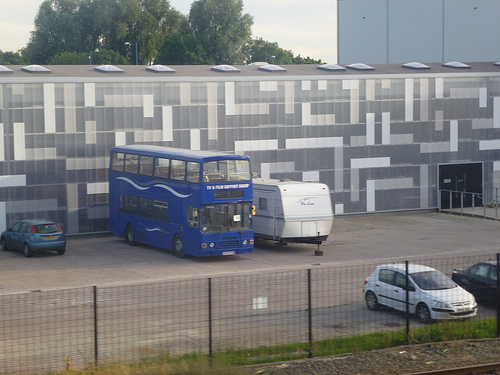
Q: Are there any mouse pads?
A: No, there are no mouse pads.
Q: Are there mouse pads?
A: No, there are no mouse pads.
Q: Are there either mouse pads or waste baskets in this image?
A: No, there are no mouse pads or waste baskets.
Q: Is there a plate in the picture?
A: Yes, there is a plate.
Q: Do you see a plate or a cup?
A: Yes, there is a plate.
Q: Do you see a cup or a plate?
A: Yes, there is a plate.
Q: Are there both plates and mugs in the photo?
A: No, there is a plate but no mugs.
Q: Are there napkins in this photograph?
A: No, there are no napkins.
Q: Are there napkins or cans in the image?
A: No, there are no napkins or cans.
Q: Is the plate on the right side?
A: No, the plate is on the left of the image.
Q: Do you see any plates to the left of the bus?
A: Yes, there is a plate to the left of the bus.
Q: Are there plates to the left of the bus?
A: Yes, there is a plate to the left of the bus.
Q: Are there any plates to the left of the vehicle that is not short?
A: Yes, there is a plate to the left of the bus.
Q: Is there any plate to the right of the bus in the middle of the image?
A: No, the plate is to the left of the bus.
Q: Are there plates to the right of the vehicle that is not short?
A: No, the plate is to the left of the bus.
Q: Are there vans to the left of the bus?
A: No, there is a plate to the left of the bus.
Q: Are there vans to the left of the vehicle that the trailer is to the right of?
A: No, there is a plate to the left of the bus.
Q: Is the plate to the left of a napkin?
A: No, the plate is to the left of the bus.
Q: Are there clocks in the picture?
A: No, there are no clocks.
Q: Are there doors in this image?
A: Yes, there is a door.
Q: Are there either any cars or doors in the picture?
A: Yes, there is a door.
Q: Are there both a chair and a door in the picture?
A: No, there is a door but no chairs.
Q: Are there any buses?
A: Yes, there is a bus.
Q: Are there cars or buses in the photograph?
A: Yes, there is a bus.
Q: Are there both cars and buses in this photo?
A: Yes, there are both a bus and a car.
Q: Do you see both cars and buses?
A: Yes, there are both a bus and a car.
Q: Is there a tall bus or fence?
A: Yes, there is a tall bus.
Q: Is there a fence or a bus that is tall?
A: Yes, the bus is tall.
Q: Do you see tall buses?
A: Yes, there is a tall bus.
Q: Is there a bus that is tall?
A: Yes, there is a bus that is tall.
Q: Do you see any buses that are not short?
A: Yes, there is a tall bus.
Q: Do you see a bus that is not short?
A: Yes, there is a tall bus.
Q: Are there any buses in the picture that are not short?
A: Yes, there is a tall bus.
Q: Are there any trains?
A: No, there are no trains.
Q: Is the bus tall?
A: Yes, the bus is tall.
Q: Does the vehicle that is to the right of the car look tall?
A: Yes, the bus is tall.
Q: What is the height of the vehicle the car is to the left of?
A: The bus is tall.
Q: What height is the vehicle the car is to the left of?
A: The bus is tall.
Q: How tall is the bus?
A: The bus is tall.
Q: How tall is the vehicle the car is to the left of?
A: The bus is tall.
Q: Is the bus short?
A: No, the bus is tall.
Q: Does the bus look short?
A: No, the bus is tall.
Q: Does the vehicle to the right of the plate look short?
A: No, the bus is tall.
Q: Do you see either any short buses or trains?
A: No, there is a bus but it is tall.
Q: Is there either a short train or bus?
A: No, there is a bus but it is tall.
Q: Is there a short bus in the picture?
A: No, there is a bus but it is tall.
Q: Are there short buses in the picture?
A: No, there is a bus but it is tall.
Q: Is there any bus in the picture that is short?
A: No, there is a bus but it is tall.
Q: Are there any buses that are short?
A: No, there is a bus but it is tall.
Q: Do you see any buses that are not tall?
A: No, there is a bus but it is tall.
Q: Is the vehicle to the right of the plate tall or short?
A: The bus is tall.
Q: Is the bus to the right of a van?
A: No, the bus is to the right of the car.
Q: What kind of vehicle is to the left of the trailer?
A: The vehicle is a bus.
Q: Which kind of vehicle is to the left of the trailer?
A: The vehicle is a bus.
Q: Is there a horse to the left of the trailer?
A: No, there is a bus to the left of the trailer.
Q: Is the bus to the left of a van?
A: No, the bus is to the left of the trailer.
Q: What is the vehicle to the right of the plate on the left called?
A: The vehicle is a bus.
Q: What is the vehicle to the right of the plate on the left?
A: The vehicle is a bus.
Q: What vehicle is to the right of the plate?
A: The vehicle is a bus.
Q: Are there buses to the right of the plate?
A: Yes, there is a bus to the right of the plate.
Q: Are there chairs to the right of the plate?
A: No, there is a bus to the right of the plate.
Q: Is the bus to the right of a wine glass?
A: No, the bus is to the right of the plate.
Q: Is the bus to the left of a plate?
A: No, the bus is to the right of a plate.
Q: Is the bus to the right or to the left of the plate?
A: The bus is to the right of the plate.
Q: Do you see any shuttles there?
A: No, there are no shuttles.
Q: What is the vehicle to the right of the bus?
A: The vehicle is a trailer.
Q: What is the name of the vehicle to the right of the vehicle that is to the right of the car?
A: The vehicle is a trailer.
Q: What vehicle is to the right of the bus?
A: The vehicle is a trailer.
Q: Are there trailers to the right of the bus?
A: Yes, there is a trailer to the right of the bus.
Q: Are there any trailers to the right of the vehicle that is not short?
A: Yes, there is a trailer to the right of the bus.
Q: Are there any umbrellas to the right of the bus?
A: No, there is a trailer to the right of the bus.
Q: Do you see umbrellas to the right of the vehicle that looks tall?
A: No, there is a trailer to the right of the bus.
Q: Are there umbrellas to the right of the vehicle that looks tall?
A: No, there is a trailer to the right of the bus.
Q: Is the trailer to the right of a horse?
A: No, the trailer is to the right of the bus.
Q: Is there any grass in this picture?
A: Yes, there is grass.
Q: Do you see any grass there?
A: Yes, there is grass.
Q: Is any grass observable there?
A: Yes, there is grass.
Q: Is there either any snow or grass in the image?
A: Yes, there is grass.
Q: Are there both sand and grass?
A: No, there is grass but no sand.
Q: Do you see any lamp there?
A: No, there are no lamps.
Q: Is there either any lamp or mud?
A: No, there are no lamps or mud.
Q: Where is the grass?
A: The grass is on the ground.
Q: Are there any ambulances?
A: No, there are no ambulances.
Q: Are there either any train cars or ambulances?
A: No, there are no ambulances or train cars.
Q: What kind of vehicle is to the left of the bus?
A: The vehicle is a car.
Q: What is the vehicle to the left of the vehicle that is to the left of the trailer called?
A: The vehicle is a car.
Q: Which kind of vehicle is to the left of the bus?
A: The vehicle is a car.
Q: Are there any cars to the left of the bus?
A: Yes, there is a car to the left of the bus.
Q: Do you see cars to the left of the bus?
A: Yes, there is a car to the left of the bus.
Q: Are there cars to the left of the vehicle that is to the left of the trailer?
A: Yes, there is a car to the left of the bus.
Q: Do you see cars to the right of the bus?
A: No, the car is to the left of the bus.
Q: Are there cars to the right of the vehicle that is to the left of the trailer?
A: No, the car is to the left of the bus.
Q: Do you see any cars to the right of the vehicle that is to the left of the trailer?
A: No, the car is to the left of the bus.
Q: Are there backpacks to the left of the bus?
A: No, there is a car to the left of the bus.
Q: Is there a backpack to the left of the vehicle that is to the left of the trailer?
A: No, there is a car to the left of the bus.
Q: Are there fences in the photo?
A: Yes, there is a fence.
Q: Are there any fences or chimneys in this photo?
A: Yes, there is a fence.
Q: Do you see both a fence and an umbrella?
A: No, there is a fence but no umbrellas.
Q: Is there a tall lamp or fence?
A: Yes, there is a tall fence.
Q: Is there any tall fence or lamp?
A: Yes, there is a tall fence.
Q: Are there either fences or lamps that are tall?
A: Yes, the fence is tall.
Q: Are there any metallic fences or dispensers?
A: Yes, there is a metal fence.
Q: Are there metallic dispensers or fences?
A: Yes, there is a metal fence.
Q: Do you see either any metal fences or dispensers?
A: Yes, there is a metal fence.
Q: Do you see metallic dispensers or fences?
A: Yes, there is a metal fence.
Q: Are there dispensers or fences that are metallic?
A: Yes, the fence is metallic.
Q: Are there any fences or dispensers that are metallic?
A: Yes, the fence is metallic.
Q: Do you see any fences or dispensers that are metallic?
A: Yes, the fence is metallic.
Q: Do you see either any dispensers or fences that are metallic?
A: Yes, the fence is metallic.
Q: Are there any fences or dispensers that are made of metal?
A: Yes, the fence is made of metal.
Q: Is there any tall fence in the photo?
A: Yes, there is a tall fence.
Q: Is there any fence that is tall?
A: Yes, there is a fence that is tall.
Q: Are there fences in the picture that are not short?
A: Yes, there is a tall fence.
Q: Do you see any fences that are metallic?
A: Yes, there is a metal fence.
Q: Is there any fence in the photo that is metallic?
A: Yes, there is a fence that is metallic.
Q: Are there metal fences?
A: Yes, there is a fence that is made of metal.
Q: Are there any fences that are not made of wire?
A: Yes, there is a fence that is made of metal.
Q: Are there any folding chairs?
A: No, there are no folding chairs.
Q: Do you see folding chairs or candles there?
A: No, there are no folding chairs or candles.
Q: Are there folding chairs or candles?
A: No, there are no folding chairs or candles.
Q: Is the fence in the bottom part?
A: Yes, the fence is in the bottom of the image.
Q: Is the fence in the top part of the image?
A: No, the fence is in the bottom of the image.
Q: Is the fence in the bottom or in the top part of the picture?
A: The fence is in the bottom of the image.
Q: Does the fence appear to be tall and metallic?
A: Yes, the fence is tall and metallic.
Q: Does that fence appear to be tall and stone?
A: No, the fence is tall but metallic.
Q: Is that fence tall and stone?
A: No, the fence is tall but metallic.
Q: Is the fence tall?
A: Yes, the fence is tall.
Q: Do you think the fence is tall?
A: Yes, the fence is tall.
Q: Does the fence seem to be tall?
A: Yes, the fence is tall.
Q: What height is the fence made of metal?
A: The fence is tall.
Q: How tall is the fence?
A: The fence is tall.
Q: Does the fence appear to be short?
A: No, the fence is tall.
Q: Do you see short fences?
A: No, there is a fence but it is tall.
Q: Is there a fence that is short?
A: No, there is a fence but it is tall.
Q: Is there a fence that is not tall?
A: No, there is a fence but it is tall.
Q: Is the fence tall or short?
A: The fence is tall.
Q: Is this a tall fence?
A: Yes, this is a tall fence.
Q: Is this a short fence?
A: No, this is a tall fence.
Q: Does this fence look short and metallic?
A: No, the fence is metallic but tall.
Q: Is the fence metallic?
A: Yes, the fence is metallic.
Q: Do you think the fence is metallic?
A: Yes, the fence is metallic.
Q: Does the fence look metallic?
A: Yes, the fence is metallic.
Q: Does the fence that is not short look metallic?
A: Yes, the fence is metallic.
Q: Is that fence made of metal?
A: Yes, the fence is made of metal.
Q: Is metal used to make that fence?
A: Yes, the fence is made of metal.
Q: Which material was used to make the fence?
A: The fence is made of metal.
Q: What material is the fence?
A: The fence is made of metal.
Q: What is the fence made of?
A: The fence is made of metal.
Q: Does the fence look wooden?
A: No, the fence is metallic.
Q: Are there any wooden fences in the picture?
A: No, there is a fence but it is metallic.